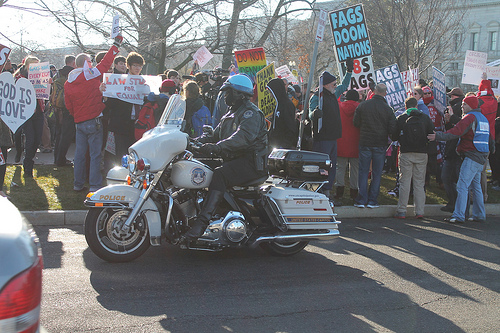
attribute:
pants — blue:
[452, 155, 487, 218]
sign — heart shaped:
[1, 71, 36, 140]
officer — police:
[169, 70, 271, 247]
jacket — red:
[61, 66, 116, 126]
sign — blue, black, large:
[327, 4, 375, 93]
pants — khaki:
[385, 139, 442, 231]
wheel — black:
[85, 207, 145, 259]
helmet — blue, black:
[217, 72, 257, 96]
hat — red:
[461, 96, 481, 108]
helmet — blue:
[218, 74, 250, 96]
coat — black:
[201, 103, 281, 163]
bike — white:
[82, 96, 342, 266]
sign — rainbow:
[315, 0, 405, 115]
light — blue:
[117, 150, 134, 169]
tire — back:
[246, 209, 313, 256]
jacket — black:
[348, 92, 401, 154]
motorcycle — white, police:
[81, 90, 344, 264]